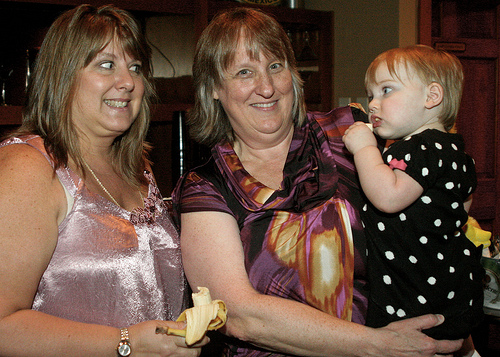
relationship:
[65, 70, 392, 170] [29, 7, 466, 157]
three people have hair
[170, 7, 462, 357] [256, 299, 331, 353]
woman has freckles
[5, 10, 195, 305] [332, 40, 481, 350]
woman looking at baby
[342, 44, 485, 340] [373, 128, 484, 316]
baby wearing dress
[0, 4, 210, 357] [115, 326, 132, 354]
woman wearing watch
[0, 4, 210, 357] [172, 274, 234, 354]
woman held banana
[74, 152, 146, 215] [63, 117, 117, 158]
necklace on neck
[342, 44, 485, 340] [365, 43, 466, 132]
baby has hair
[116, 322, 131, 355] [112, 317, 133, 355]
watch around wrist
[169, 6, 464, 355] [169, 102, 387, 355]
woman wearing a shirt